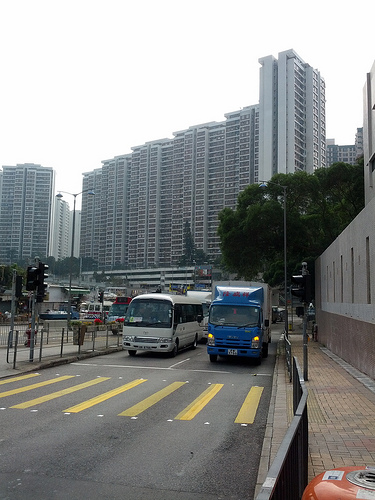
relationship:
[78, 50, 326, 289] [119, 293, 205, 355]
building behind bus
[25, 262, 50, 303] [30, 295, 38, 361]
traffic light on pole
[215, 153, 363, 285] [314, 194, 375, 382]
trees behind wall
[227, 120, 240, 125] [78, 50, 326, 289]
window on building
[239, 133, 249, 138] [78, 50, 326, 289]
window on building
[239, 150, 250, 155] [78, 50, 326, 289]
window on building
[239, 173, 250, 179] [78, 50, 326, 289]
window on building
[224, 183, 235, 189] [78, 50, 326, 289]
window on building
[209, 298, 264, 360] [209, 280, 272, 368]
front of truck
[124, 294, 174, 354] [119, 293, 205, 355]
front of bus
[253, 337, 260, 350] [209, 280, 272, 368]
headlight of truck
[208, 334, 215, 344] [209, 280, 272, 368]
headlight of truck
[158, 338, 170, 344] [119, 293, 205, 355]
headlight of bus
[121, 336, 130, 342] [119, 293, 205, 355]
headlight of bus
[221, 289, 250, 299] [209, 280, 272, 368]
writing on truck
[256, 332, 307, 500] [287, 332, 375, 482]
barrier next to sidewalk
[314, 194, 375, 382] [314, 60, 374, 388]
wall of building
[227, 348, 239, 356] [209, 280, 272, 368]
license plate on truck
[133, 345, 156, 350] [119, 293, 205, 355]
license plate on bus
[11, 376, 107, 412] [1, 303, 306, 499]
line on road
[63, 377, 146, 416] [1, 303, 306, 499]
line on road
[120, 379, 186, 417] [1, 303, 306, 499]
line on road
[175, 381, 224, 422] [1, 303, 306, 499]
line on road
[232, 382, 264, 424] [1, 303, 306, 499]
line on road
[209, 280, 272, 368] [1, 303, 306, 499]
truck on road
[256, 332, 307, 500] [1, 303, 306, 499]
barrier near road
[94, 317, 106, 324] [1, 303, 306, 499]
flowers near road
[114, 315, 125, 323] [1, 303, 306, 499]
flowers near road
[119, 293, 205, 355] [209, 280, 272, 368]
bus next to truck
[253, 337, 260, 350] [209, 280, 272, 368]
headlight on truck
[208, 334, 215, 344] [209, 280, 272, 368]
headlight on truck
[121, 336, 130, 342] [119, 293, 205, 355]
headlight on bus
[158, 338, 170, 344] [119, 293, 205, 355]
headlight on bus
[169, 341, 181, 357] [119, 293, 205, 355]
wheel on bus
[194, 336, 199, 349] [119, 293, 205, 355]
wheel on bus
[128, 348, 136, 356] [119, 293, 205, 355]
wheel on bus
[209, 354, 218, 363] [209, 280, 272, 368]
wheel on truck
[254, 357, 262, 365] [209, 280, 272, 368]
wheel on truck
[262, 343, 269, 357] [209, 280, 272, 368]
wheel on truck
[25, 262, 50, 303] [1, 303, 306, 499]
traffic light next to road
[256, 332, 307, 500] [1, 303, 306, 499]
barrier next to road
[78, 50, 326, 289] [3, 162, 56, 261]
building beside building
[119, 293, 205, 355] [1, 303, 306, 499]
bus on road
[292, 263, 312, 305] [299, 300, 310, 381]
traffic light on pole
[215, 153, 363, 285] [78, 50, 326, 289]
trees next to building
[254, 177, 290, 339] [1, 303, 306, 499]
light pole next to road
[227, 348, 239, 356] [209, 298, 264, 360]
license plate on front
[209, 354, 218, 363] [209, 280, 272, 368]
wheel of truck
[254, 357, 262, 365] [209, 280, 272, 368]
wheel of truck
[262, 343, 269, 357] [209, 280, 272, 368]
wheel of truck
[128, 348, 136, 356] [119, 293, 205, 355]
wheel of bus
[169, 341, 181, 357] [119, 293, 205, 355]
wheel of bus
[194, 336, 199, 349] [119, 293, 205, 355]
wheel of bus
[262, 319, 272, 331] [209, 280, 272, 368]
side mirror of truck